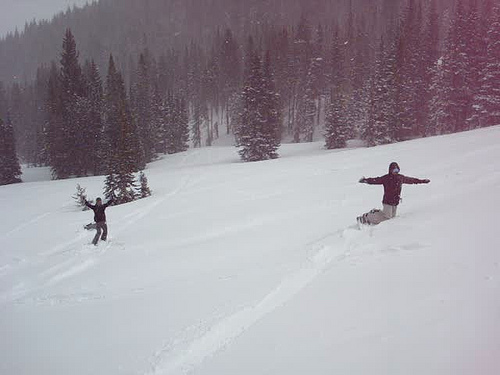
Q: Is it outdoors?
A: Yes, it is outdoors.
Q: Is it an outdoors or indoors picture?
A: It is outdoors.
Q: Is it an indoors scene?
A: No, it is outdoors.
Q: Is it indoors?
A: No, it is outdoors.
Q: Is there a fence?
A: No, there are no fences.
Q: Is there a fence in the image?
A: No, there are no fences.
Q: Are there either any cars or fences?
A: No, there are no fences or cars.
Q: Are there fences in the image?
A: No, there are no fences.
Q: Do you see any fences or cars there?
A: No, there are no fences or cars.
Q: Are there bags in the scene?
A: No, there are no bags.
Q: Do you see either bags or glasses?
A: No, there are no bags or glasses.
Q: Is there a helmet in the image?
A: No, there are no helmets.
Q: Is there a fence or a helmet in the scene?
A: No, there are no helmets or fences.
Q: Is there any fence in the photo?
A: No, there are no fences.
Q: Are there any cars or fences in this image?
A: No, there are no fences or cars.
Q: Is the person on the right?
A: Yes, the person is on the right of the image.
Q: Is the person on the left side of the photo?
A: No, the person is on the right of the image.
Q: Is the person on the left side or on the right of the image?
A: The person is on the right of the image.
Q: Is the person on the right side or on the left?
A: The person is on the right of the image.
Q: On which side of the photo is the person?
A: The person is on the right of the image.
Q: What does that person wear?
A: The person wears a jacket.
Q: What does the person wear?
A: The person wears a jacket.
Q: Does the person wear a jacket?
A: Yes, the person wears a jacket.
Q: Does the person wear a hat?
A: No, the person wears a jacket.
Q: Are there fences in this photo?
A: No, there are no fences.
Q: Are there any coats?
A: Yes, there is a coat.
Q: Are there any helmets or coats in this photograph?
A: Yes, there is a coat.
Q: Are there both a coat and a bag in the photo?
A: No, there is a coat but no bags.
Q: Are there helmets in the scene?
A: No, there are no helmets.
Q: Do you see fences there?
A: No, there are no fences.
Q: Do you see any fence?
A: No, there are no fences.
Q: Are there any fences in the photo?
A: No, there are no fences.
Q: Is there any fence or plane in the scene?
A: No, there are no fences or airplanes.